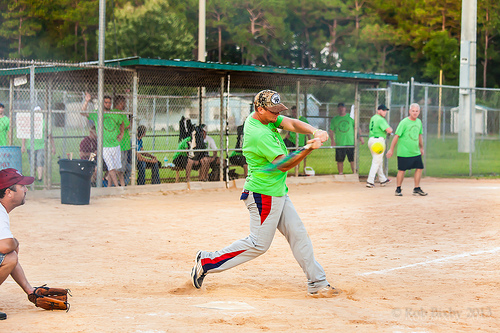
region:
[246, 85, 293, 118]
Man in baseball cap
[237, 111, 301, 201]
Man in green shirt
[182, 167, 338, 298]
Man wearing long pants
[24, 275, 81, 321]
person holding baseball glove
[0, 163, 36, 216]
Man wearing a red hat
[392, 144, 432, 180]
Man wearing black shorts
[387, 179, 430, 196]
Man wearing black socks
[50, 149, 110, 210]
Blue trash can on dirt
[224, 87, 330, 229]
Man swinging a bat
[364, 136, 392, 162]
A yellow softball in flight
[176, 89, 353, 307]
player swinging bat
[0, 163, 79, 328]
catcher crouched behind home plate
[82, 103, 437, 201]
team wearing green shirts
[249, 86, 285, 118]
hat of man swinging bat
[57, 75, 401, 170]
dugout green team is in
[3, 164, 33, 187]
red hat of catcher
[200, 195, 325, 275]
gray, red, and black pants of batter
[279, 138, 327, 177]
bat being swung by plater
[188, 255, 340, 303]
cleats of player at bat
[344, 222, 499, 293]
white chalk on field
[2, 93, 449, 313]
Men are playing baseball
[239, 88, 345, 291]
Man is ready to hit ball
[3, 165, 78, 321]
Catcher is ready to catch ball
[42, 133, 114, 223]
Can full of baseball bats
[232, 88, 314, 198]
Man is wearing green shirt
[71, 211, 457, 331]
Baseball field is made of dirt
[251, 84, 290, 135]
Man is wearing camo capon on his head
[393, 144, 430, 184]
Man is wearing black shorts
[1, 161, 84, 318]
Catcher has his glove on ground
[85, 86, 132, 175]
Player is watching game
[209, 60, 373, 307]
man swinging bat on baseball field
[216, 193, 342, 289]
gray,red, and black pants on batter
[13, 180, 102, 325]
catcher standing behind batter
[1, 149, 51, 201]
red hat on catcher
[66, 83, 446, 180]
team in dugout by field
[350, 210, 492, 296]
white line on dirt ground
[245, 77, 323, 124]
brown and green hat on batter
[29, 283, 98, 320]
catcher's mitt on man's hand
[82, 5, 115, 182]
metal pole by dugout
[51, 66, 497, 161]
metal chain link fence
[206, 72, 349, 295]
man wearing a hat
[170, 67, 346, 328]
man wearing a green shirt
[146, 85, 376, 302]
man wearing gray pants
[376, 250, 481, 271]
line on a field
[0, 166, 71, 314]
man wearing a hat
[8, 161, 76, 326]
man holding a glove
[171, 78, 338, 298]
man holding a bat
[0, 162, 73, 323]
man wearing a gray shirt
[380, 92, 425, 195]
man wearing green shirt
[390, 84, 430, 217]
man wearing a black shorts